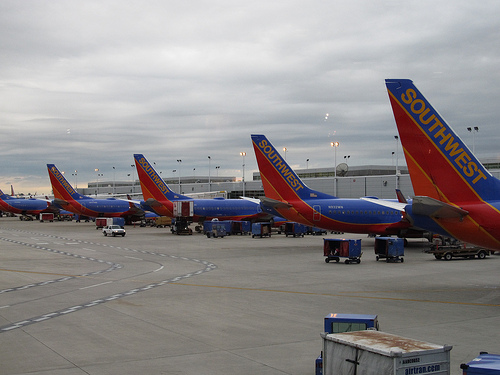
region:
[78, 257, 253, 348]
The ground is made of concrete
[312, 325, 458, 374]
The white container on the ground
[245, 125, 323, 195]
The back wing of the plane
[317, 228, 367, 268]
The luggage carts on the ground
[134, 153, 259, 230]
The plane is blue and red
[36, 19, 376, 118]
The sky is a little cloudy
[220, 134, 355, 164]
The lights on the building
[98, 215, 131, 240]
The car is driving on the ground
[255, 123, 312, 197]
The words say "Southwest"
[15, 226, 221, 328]
The lines on the ground are black and white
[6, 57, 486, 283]
a row of airplanes at an airport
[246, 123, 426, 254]
southwest airlines airplane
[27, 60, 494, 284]
a row of southwest airlines planes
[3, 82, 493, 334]
planes parked at an airport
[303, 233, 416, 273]
containers with luggage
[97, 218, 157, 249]
a white car driving at an airport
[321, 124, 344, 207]
a light post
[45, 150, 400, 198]
a row of light posts at an airport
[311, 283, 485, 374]
a vehicle carrying containers of luggage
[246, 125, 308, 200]
the wing of a southwest airplane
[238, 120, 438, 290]
This is an aircraft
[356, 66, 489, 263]
This is an aircraft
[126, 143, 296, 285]
This is an aircraft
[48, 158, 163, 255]
This is an aircraft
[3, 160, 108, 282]
This is an aircraft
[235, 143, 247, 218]
This is an electric pole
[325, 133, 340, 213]
This is an electric pole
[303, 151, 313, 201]
This is an electric pole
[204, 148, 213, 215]
This is an electric pole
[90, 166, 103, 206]
This is an electric pole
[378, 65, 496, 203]
vertical stabilizer of plane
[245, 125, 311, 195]
vertical stabilizer of plane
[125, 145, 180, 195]
vertical stabilizer of plane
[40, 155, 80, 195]
vertical stabilizer of plane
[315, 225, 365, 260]
car is color blue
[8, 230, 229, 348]
white lines on the road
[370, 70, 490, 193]
tail is color red and yellow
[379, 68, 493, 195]
yellow work on vertical stabilizer